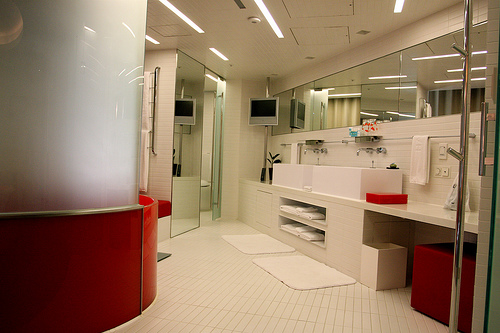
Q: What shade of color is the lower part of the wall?
A: Red.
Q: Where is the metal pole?
A: Right side of photo.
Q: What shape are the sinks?
A: Square.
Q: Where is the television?
A: In the corner by the mirror.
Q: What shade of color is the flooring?
A: White.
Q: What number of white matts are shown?
A: 2.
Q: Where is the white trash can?
A: Under the counter.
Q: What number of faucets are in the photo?
A: 2.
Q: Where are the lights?
A: Ceiling.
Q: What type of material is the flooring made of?
A: Tile.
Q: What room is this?
A: A bathroom.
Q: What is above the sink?
A: A mirror.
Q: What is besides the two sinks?
A: A metal towel rack.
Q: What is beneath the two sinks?
A: Bathroom rugs.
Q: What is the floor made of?
A: Tile.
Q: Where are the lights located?
A: Ceiling.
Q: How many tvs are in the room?
A: 1.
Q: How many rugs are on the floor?
A: 2.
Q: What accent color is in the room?
A: Red.